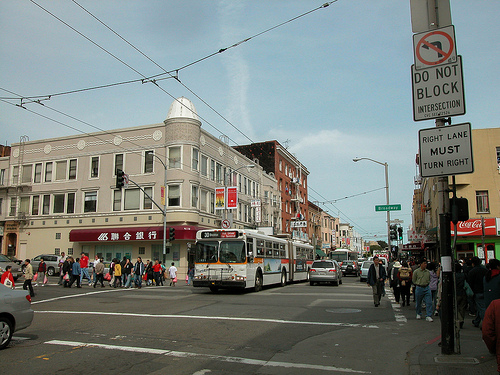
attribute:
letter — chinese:
[96, 229, 110, 243]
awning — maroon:
[68, 226, 213, 244]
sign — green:
[373, 202, 404, 214]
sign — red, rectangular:
[447, 215, 500, 242]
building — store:
[427, 120, 500, 320]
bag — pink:
[31, 269, 40, 287]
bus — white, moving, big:
[192, 225, 320, 293]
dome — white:
[159, 88, 205, 129]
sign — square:
[409, 22, 459, 72]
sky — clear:
[0, 2, 499, 245]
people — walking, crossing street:
[1, 249, 181, 300]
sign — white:
[410, 52, 469, 123]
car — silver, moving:
[307, 254, 345, 289]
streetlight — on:
[397, 222, 406, 245]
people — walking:
[362, 247, 499, 364]